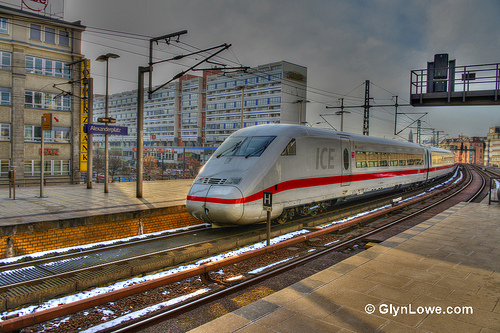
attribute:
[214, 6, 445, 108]
clouds — blue, white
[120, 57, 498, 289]
train — red and silver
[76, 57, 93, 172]
sign — yellow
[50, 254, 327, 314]
train tracks — snow covered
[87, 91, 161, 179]
sign — blue